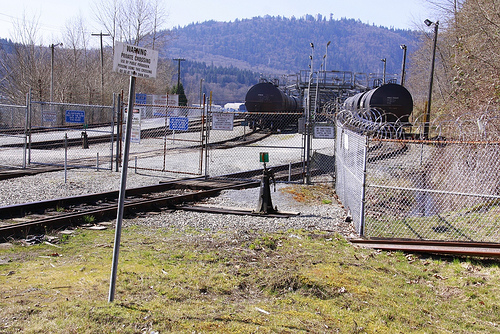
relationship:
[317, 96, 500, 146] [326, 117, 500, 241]
wire on top of fence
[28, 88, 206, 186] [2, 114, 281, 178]
gate crosses tracks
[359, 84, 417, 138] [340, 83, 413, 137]
cars of cars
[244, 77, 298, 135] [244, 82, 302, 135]
cars of cars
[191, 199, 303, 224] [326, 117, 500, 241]
plank under fence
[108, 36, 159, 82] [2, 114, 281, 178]
sign beside tracks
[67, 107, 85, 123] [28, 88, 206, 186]
sign on gate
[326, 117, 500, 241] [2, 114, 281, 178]
fence near tracks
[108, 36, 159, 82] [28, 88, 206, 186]
sign on gate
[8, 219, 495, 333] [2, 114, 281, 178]
grass near tracks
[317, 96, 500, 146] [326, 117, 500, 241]
wire atop fence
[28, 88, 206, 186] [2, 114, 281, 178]
gate above tracks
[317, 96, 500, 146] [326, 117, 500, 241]
wire on fence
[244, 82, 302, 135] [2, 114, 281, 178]
cars on tracks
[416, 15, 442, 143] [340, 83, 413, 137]
lamp above cars